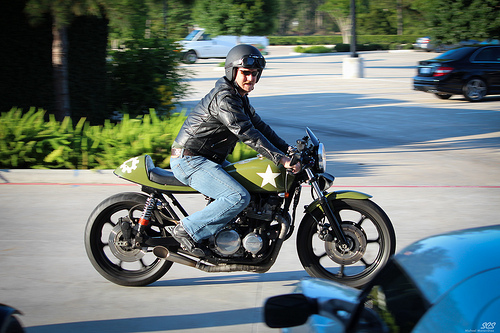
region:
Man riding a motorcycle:
[82, 40, 407, 290]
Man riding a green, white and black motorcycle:
[80, 38, 403, 289]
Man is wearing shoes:
[167, 222, 204, 257]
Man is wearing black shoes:
[167, 217, 208, 259]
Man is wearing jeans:
[161, 141, 249, 241]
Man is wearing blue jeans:
[166, 142, 254, 244]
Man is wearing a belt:
[168, 140, 203, 157]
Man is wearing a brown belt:
[170, 142, 203, 155]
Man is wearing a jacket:
[173, 75, 296, 168]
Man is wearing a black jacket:
[169, 76, 297, 164]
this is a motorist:
[155, 33, 283, 221]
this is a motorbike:
[278, 136, 348, 268]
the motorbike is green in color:
[235, 164, 277, 182]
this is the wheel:
[354, 204, 387, 255]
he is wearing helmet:
[230, 45, 263, 62]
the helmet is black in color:
[226, 42, 246, 57]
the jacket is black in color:
[181, 88, 244, 146]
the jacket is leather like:
[184, 95, 246, 148]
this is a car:
[412, 41, 497, 92]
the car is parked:
[417, 42, 497, 106]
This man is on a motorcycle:
[8, 24, 499, 279]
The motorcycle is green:
[112, 150, 317, 223]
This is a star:
[249, 154, 334, 214]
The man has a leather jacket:
[165, 77, 287, 157]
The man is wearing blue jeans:
[173, 163, 288, 253]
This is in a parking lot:
[20, 58, 492, 309]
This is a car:
[400, 39, 495, 122]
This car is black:
[394, 28, 496, 107]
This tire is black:
[298, 195, 420, 293]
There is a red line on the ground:
[20, 176, 120, 204]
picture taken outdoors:
[21, 18, 414, 324]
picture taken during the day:
[10, 7, 375, 292]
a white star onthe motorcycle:
[255, 160, 276, 190]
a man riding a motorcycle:
[45, 0, 415, 325]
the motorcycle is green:
[120, 140, 315, 210]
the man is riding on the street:
[41, 56, 378, 308]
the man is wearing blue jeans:
[191, 162, 213, 186]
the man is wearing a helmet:
[228, 30, 258, 90]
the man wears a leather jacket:
[204, 100, 231, 150]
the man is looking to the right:
[227, 35, 272, 96]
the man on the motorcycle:
[83, 43, 395, 285]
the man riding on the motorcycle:
[85, 43, 397, 287]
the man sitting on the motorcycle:
[84, 43, 396, 286]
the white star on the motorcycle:
[257, 163, 281, 188]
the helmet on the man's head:
[226, 43, 266, 88]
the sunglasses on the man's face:
[235, 67, 260, 77]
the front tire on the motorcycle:
[296, 198, 397, 288]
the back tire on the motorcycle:
[83, 190, 177, 284]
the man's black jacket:
[174, 75, 289, 163]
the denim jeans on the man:
[168, 152, 251, 243]